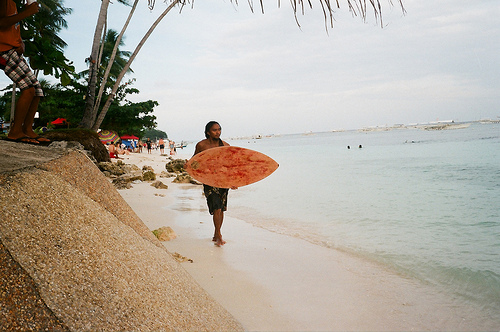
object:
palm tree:
[31, 2, 171, 171]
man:
[1, 0, 53, 146]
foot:
[22, 130, 55, 143]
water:
[178, 120, 498, 329]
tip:
[263, 155, 280, 176]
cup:
[23, 0, 40, 6]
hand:
[21, 0, 37, 17]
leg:
[204, 189, 227, 245]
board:
[182, 145, 280, 190]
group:
[157, 137, 167, 154]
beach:
[90, 129, 495, 330]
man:
[184, 120, 279, 247]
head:
[345, 145, 350, 150]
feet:
[1, 132, 44, 146]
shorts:
[0, 46, 47, 98]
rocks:
[108, 199, 235, 307]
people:
[137, 137, 145, 152]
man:
[145, 136, 154, 153]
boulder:
[18, 162, 169, 330]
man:
[347, 145, 352, 149]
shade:
[27, 122, 75, 148]